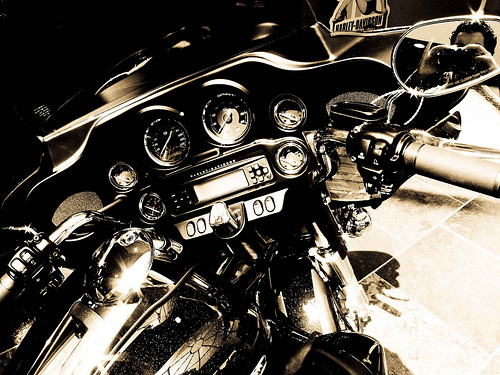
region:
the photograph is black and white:
[1, 3, 498, 373]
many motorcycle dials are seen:
[100, 100, 333, 246]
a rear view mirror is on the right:
[388, 11, 498, 94]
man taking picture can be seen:
[417, 21, 497, 82]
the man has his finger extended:
[422, 33, 433, 59]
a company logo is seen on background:
[310, 2, 397, 52]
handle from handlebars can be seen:
[402, 137, 497, 192]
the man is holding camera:
[416, 22, 496, 82]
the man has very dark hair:
[448, 20, 494, 66]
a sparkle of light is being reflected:
[109, 255, 146, 302]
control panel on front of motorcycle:
[28, 38, 429, 350]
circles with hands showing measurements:
[130, 80, 267, 166]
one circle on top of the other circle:
[251, 85, 326, 195]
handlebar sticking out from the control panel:
[255, 97, 490, 228]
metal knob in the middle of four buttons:
[165, 190, 285, 245]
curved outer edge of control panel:
[35, 40, 385, 185]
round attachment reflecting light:
[86, 231, 163, 311]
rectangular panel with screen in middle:
[150, 146, 290, 213]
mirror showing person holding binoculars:
[366, 6, 492, 103]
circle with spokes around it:
[155, 305, 230, 370]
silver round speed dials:
[142, 87, 254, 167]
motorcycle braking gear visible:
[360, 115, 495, 205]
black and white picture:
[5, 0, 498, 365]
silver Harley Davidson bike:
[2, 0, 497, 370]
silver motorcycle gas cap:
[33, 225, 238, 368]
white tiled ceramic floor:
[337, 85, 497, 367]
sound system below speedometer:
[162, 141, 287, 254]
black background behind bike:
[5, 0, 495, 371]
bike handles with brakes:
[0, 117, 497, 312]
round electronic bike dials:
[106, 83, 311, 233]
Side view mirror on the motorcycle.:
[397, 11, 498, 85]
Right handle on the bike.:
[346, 134, 476, 229]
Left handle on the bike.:
[2, 225, 84, 272]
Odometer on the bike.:
[196, 96, 263, 141]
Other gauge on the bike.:
[136, 120, 194, 158]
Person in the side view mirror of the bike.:
[419, 30, 492, 72]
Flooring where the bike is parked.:
[404, 219, 476, 323]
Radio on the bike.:
[177, 163, 272, 212]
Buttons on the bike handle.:
[355, 129, 395, 180]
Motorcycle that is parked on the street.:
[40, 57, 455, 344]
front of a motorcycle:
[19, 41, 486, 338]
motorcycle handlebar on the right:
[363, 125, 498, 206]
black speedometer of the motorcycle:
[137, 112, 198, 169]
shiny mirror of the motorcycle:
[389, 8, 499, 94]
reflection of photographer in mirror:
[397, 15, 499, 100]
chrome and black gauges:
[107, 81, 318, 219]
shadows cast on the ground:
[360, 247, 407, 315]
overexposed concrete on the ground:
[399, 210, 481, 358]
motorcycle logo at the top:
[321, 0, 389, 30]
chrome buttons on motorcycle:
[246, 158, 273, 189]